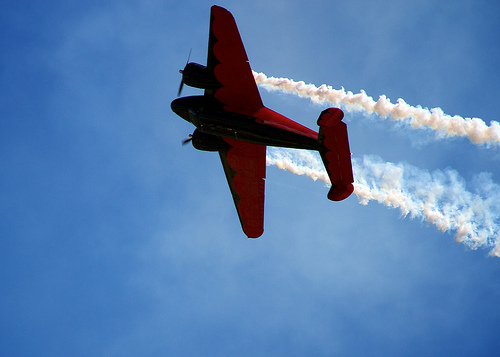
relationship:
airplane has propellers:
[169, 5, 358, 242] [156, 50, 212, 156]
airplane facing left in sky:
[169, 5, 358, 242] [0, 3, 499, 355]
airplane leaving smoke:
[169, 5, 358, 242] [250, 74, 500, 148]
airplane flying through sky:
[169, 5, 358, 242] [18, 50, 160, 326]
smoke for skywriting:
[258, 74, 468, 139] [252, 56, 492, 251]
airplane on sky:
[169, 20, 358, 224] [28, 86, 150, 326]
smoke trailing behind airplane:
[250, 74, 500, 148] [169, 5, 358, 242]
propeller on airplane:
[174, 46, 194, 95] [169, 5, 358, 242]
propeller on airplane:
[177, 128, 211, 142] [169, 5, 358, 242]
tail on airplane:
[315, 106, 356, 203] [169, 5, 358, 242]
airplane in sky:
[169, 5, 358, 242] [0, 3, 499, 355]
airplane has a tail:
[169, 5, 358, 242] [295, 93, 358, 211]